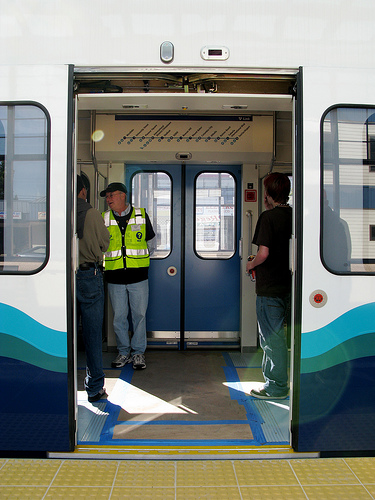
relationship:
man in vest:
[98, 178, 153, 368] [101, 208, 150, 266]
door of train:
[123, 161, 179, 348] [0, 1, 374, 457]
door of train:
[179, 161, 242, 346] [0, 1, 374, 457]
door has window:
[123, 161, 179, 348] [128, 168, 173, 261]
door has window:
[179, 161, 242, 346] [192, 165, 239, 260]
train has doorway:
[0, 1, 374, 457] [70, 65, 290, 451]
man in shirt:
[98, 178, 153, 368] [101, 211, 156, 284]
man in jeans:
[98, 178, 153, 368] [105, 283, 154, 352]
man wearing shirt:
[74, 172, 110, 403] [76, 198, 111, 266]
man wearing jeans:
[74, 172, 110, 403] [76, 269, 107, 393]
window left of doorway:
[0, 97, 49, 277] [70, 65, 290, 451]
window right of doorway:
[317, 98, 374, 275] [70, 65, 290, 451]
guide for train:
[111, 122, 251, 151] [0, 1, 374, 457]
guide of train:
[111, 122, 251, 151] [0, 1, 374, 457]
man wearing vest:
[98, 178, 153, 368] [101, 208, 150, 266]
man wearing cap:
[98, 178, 153, 368] [98, 182, 127, 197]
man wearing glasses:
[98, 178, 153, 368] [102, 190, 121, 198]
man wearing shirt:
[246, 172, 290, 402] [255, 205, 290, 298]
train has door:
[0, 1, 374, 457] [123, 161, 179, 348]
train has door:
[0, 1, 374, 457] [179, 161, 242, 346]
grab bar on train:
[91, 166, 101, 206] [0, 1, 374, 457]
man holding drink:
[246, 172, 290, 402] [246, 254, 258, 281]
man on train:
[98, 178, 153, 368] [0, 1, 374, 457]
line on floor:
[117, 416, 249, 428] [82, 348, 293, 445]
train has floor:
[0, 1, 374, 457] [82, 348, 293, 445]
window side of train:
[0, 97, 49, 277] [0, 1, 374, 457]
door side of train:
[296, 67, 374, 457] [0, 1, 374, 457]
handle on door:
[310, 289, 329, 308] [296, 67, 374, 457]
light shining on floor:
[102, 375, 186, 418] [82, 348, 293, 445]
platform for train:
[2, 460, 374, 497] [0, 1, 374, 457]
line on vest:
[104, 248, 149, 259] [101, 208, 150, 266]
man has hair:
[246, 172, 290, 402] [264, 169, 292, 204]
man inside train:
[98, 178, 153, 368] [0, 1, 374, 457]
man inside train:
[246, 172, 290, 402] [0, 1, 374, 457]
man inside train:
[74, 172, 110, 403] [0, 1, 374, 457]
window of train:
[0, 97, 49, 277] [0, 1, 374, 457]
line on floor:
[220, 348, 263, 443] [82, 348, 293, 445]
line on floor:
[78, 438, 290, 447] [82, 348, 293, 445]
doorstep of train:
[76, 442, 294, 453] [0, 1, 374, 457]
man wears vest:
[98, 178, 153, 368] [101, 208, 150, 266]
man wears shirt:
[246, 172, 290, 402] [255, 205, 290, 298]